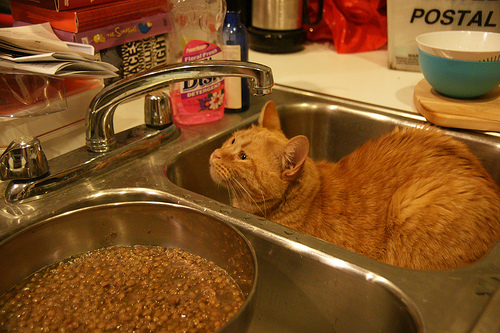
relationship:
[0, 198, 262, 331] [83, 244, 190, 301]
bowl of beans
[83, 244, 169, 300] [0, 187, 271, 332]
beans on plate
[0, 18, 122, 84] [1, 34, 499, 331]
paper on sink table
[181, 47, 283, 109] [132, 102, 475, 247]
faucet on sink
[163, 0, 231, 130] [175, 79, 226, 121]
bottle has dish detergent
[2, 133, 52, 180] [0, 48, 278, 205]
knob on faucet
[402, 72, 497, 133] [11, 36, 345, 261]
board near sink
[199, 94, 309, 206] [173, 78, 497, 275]
head on cat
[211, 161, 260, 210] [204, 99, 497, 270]
whiskers on cat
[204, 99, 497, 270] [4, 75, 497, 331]
cat in sink